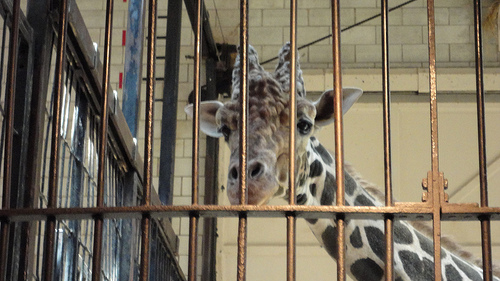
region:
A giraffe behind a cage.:
[141, 38, 451, 252]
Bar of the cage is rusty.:
[319, 20, 487, 212]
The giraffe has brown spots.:
[287, 154, 429, 274]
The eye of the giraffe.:
[275, 109, 327, 146]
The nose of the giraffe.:
[227, 164, 279, 188]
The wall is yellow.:
[338, 40, 475, 195]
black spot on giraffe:
[307, 158, 324, 178]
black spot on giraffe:
[293, 190, 306, 202]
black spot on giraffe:
[308, 178, 316, 199]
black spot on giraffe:
[323, 168, 336, 204]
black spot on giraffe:
[322, 224, 341, 255]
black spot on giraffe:
[349, 257, 382, 278]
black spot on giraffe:
[349, 225, 361, 246]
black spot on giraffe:
[362, 222, 382, 260]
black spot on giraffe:
[391, 219, 411, 243]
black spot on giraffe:
[413, 225, 444, 256]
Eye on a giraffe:
[293, 116, 310, 132]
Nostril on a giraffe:
[241, 158, 263, 178]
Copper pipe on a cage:
[97, 2, 107, 204]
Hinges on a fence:
[416, 168, 451, 206]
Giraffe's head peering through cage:
[182, 35, 362, 203]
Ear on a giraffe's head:
[182, 101, 219, 137]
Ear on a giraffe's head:
[313, 85, 362, 122]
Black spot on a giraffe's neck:
[303, 157, 323, 179]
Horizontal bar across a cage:
[4, 204, 498, 219]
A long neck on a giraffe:
[294, 148, 472, 280]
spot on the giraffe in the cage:
[305, 158, 322, 180]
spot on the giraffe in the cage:
[304, 173, 324, 205]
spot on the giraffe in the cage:
[320, 224, 342, 259]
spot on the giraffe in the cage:
[320, 168, 337, 204]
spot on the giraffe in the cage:
[366, 220, 391, 266]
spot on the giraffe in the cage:
[350, 255, 385, 279]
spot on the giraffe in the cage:
[393, 218, 415, 245]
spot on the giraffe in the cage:
[397, 245, 429, 280]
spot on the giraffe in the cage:
[410, 225, 446, 268]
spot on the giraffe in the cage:
[451, 250, 478, 279]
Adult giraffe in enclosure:
[184, 39, 491, 279]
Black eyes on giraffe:
[216, 117, 313, 140]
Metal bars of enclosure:
[2, 2, 498, 279]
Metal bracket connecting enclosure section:
[390, 169, 482, 209]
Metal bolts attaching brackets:
[420, 178, 450, 203]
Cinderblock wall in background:
[15, 0, 493, 277]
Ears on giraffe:
[182, 83, 364, 137]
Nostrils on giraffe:
[225, 160, 265, 182]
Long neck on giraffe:
[293, 137, 496, 279]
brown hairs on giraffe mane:
[317, 140, 497, 273]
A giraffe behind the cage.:
[222, 35, 415, 265]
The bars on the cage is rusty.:
[118, 25, 474, 247]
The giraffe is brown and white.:
[198, 49, 398, 276]